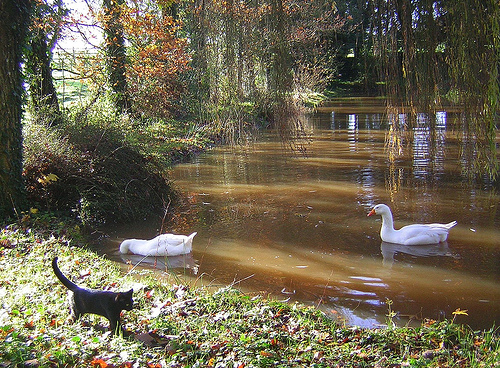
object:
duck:
[366, 202, 458, 246]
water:
[282, 153, 369, 203]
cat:
[51, 257, 134, 336]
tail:
[51, 256, 78, 292]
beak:
[367, 207, 377, 216]